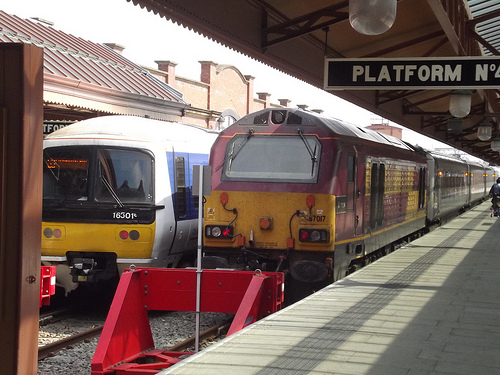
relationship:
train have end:
[199, 107, 500, 278] [200, 107, 337, 250]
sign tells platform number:
[324, 56, 500, 90] [351, 64, 500, 82]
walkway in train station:
[155, 196, 499, 374] [4, 2, 499, 374]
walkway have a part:
[155, 196, 499, 374] [394, 256, 433, 316]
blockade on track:
[91, 269, 286, 374] [37, 299, 250, 374]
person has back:
[488, 175, 499, 219] [492, 183, 500, 200]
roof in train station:
[128, 4, 494, 163] [4, 2, 499, 374]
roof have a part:
[128, 4, 494, 163] [233, 4, 318, 38]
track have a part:
[37, 299, 250, 374] [58, 318, 97, 356]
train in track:
[199, 107, 500, 278] [37, 299, 250, 374]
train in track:
[42, 116, 220, 270] [37, 299, 250, 374]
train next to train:
[199, 107, 500, 278] [42, 116, 220, 270]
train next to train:
[42, 116, 220, 270] [199, 107, 500, 278]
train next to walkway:
[199, 107, 500, 278] [155, 196, 499, 374]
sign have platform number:
[324, 56, 500, 90] [351, 64, 500, 82]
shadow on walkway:
[259, 206, 499, 374] [155, 196, 499, 374]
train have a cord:
[199, 107, 500, 278] [289, 209, 301, 239]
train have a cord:
[199, 107, 500, 278] [221, 204, 240, 227]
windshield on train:
[40, 148, 155, 214] [42, 116, 220, 270]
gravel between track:
[41, 307, 225, 368] [37, 299, 250, 374]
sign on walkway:
[324, 56, 500, 90] [155, 196, 499, 374]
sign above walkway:
[324, 56, 500, 90] [155, 196, 499, 374]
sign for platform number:
[324, 56, 500, 90] [351, 64, 500, 82]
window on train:
[225, 135, 322, 186] [199, 107, 500, 278]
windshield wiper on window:
[211, 131, 254, 175] [225, 135, 322, 186]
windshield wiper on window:
[276, 124, 318, 161] [225, 135, 322, 186]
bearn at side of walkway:
[0, 41, 44, 374] [155, 196, 499, 374]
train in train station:
[199, 107, 500, 278] [4, 2, 499, 374]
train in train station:
[42, 116, 220, 270] [4, 2, 499, 374]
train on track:
[199, 107, 500, 278] [37, 299, 250, 374]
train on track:
[42, 116, 220, 270] [37, 299, 250, 374]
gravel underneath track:
[41, 307, 225, 368] [37, 299, 250, 374]